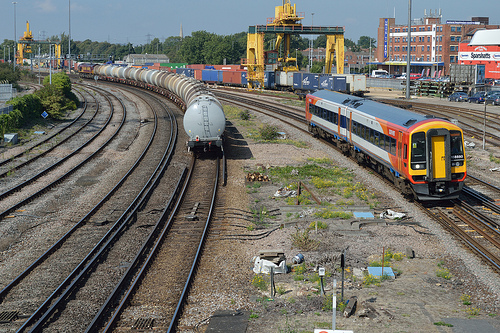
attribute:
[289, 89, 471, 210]
train — yellow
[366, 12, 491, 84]
brick building — large, red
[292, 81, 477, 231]
train — short, colorful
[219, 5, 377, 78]
crane — yellow , green 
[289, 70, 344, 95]
freight car — white, blue, red , freight 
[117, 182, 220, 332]
train tracks — metal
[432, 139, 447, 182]
door — yellow 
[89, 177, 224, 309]
tracks — train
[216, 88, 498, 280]
tracks — brown, rusted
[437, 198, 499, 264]
tracks — train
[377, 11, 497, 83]
brick building — red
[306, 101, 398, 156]
row — windowed